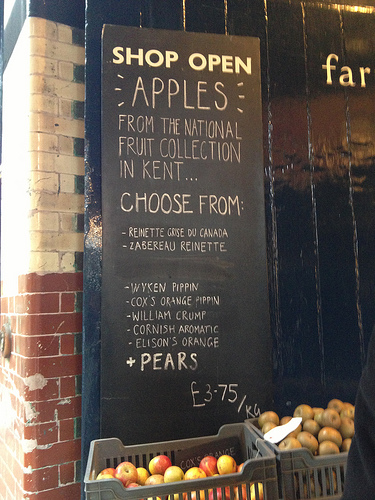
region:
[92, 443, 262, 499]
The apples in the bin that are red and yellow.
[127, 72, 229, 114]
The word Apples on the black poster.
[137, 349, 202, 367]
The word Pears on the board.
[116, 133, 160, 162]
The word Fruit on the board.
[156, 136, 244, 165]
The word Collection on the board.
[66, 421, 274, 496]
The gray bin holding the red and yellow apples.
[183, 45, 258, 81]
The word Open on the board.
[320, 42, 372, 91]
The word Far on the building.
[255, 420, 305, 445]
The white tag between the two gray bins.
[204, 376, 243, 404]
The number 3-75.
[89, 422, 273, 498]
red and yellow apples in a crate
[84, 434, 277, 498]
a grey grate with a white tag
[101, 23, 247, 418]
a chalkboard listing of apples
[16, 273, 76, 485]
red brick in a wall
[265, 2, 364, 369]
a black painted wall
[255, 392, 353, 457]
pale brown apples in a crate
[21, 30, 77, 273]
white brick in a wall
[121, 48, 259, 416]
white writing on a chalkboard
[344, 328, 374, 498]
the dark gray sleeve of a shirt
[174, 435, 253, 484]
a small sign in a crage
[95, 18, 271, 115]
shop sells apples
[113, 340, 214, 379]
shop also sells pears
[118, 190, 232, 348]
seven varieties of apples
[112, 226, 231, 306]
one variety erased from the sign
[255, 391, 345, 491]
pears in plastic crate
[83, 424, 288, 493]
apples in plastic crate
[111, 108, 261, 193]
the apples come from Kent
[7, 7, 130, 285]
sign is outside the shop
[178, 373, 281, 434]
price is 3.75 pounds per kilo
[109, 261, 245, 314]
two types of pippins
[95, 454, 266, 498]
apples are in crate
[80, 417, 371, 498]
two grey plastic crate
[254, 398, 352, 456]
apples are in crate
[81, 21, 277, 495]
sign is on the wall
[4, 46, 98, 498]
wall is made of brick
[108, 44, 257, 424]
writing is on sign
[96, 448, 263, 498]
apples are red and green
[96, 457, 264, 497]
apples are next to apples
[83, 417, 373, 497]
crates in front of sign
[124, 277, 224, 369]
words are written in chalk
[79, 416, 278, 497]
a gray plastic carton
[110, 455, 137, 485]
a red and yellow apple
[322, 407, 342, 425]
a brown pear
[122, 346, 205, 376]
white writing on the chalk board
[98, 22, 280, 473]
a black chalk board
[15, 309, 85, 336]
a red brick in the wall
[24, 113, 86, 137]
a white brick in the wall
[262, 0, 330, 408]
a black wooden board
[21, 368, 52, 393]
a white spot on the wall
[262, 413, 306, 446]
a white tag